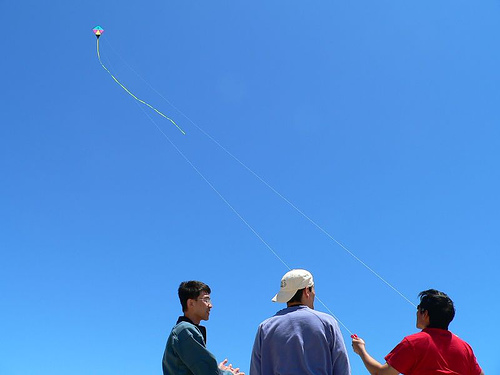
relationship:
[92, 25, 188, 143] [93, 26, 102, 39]
kite shaped like a diamond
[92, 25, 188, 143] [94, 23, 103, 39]
kite has many colors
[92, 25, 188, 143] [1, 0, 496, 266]
kite flies in air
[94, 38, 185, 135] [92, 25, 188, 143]
yellow string attached to kite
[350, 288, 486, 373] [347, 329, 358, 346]
man holding handle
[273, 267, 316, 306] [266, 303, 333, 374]
hat turned backwards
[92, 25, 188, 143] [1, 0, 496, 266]
kite flies in sky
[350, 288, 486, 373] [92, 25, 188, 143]
man flies kite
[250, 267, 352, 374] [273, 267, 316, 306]
man wears hat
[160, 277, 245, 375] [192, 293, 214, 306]
men wearing glasses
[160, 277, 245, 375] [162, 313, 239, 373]
men wearing jacket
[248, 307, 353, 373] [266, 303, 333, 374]
shirt colored blue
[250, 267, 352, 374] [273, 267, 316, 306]
man has on hat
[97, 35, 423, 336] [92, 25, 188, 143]
string attached to kite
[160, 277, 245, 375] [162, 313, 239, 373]
men wearing a purple shirt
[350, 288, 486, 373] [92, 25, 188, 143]
man holding kite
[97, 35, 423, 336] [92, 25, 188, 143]
string connects to kite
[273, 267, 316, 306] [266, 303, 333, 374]
hat worn backwards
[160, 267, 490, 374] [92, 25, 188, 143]
men are flying kites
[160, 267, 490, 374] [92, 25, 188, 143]
men look at kite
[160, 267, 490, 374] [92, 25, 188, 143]
guys flying kite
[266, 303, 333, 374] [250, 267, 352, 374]
back of a man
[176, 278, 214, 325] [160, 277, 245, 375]
head on a men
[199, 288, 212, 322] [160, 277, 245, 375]
face on a men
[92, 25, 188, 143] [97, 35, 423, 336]
kite has attached rope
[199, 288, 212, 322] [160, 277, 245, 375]
face on men